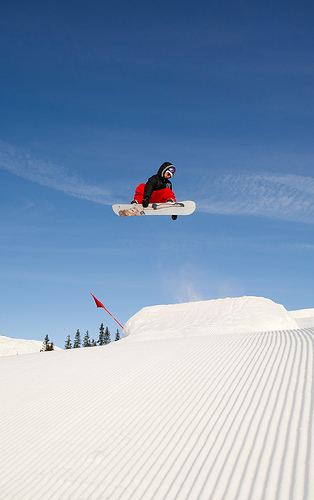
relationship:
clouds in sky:
[0, 144, 314, 226] [5, 6, 299, 323]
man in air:
[99, 145, 203, 230] [0, 0, 313, 349]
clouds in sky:
[96, 243, 171, 280] [5, 6, 299, 323]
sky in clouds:
[5, 6, 299, 323] [1, 134, 100, 213]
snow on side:
[30, 371, 244, 443] [1, 322, 313, 496]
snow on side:
[0, 294, 314, 499] [1, 295, 310, 497]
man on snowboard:
[129, 158, 177, 221] [111, 202, 194, 215]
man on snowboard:
[129, 158, 177, 221] [110, 195, 193, 215]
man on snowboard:
[129, 158, 177, 221] [106, 197, 199, 215]